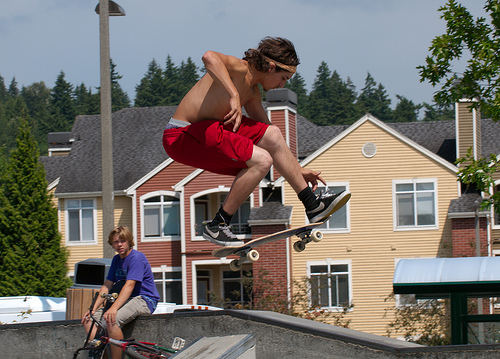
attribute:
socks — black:
[290, 182, 321, 212]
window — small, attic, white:
[360, 136, 377, 161]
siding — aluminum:
[354, 183, 391, 248]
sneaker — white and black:
[300, 188, 350, 221]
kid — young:
[78, 220, 162, 357]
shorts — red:
[150, 107, 310, 171]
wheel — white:
[291, 240, 303, 250]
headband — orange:
[247, 43, 302, 75]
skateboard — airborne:
[196, 172, 388, 283]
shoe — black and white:
[303, 190, 350, 225]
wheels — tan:
[226, 226, 325, 272]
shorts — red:
[147, 94, 331, 195]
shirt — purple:
[104, 245, 160, 306]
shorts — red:
[156, 121, 273, 177]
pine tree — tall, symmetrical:
[0, 114, 76, 298]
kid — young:
[80, 208, 165, 324]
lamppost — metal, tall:
[95, 0, 112, 257]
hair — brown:
[236, 30, 308, 90]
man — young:
[157, 31, 347, 239]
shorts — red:
[162, 116, 272, 171]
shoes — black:
[155, 169, 392, 244]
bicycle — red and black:
[68, 297, 183, 357]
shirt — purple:
[94, 251, 162, 311]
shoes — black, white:
[300, 171, 362, 234]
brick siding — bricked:
[252, 225, 292, 315]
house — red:
[124, 88, 298, 312]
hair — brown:
[242, 27, 298, 88]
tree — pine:
[8, 90, 78, 305]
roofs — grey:
[48, 54, 478, 204]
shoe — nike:
[202, 218, 243, 253]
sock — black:
[293, 183, 315, 212]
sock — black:
[213, 208, 242, 230]